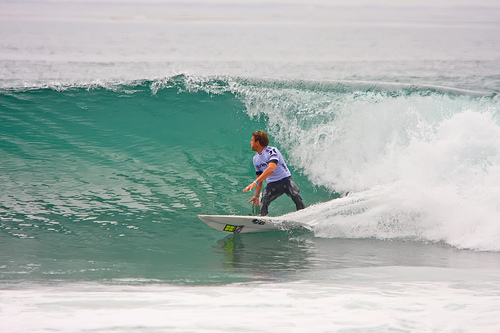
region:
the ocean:
[31, 21, 482, 318]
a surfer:
[184, 113, 381, 250]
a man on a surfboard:
[179, 113, 375, 240]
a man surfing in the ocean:
[186, 121, 403, 240]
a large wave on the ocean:
[33, 31, 473, 286]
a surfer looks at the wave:
[85, 86, 398, 247]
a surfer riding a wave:
[1, 71, 489, 244]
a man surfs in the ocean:
[187, 116, 394, 236]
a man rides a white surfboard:
[178, 103, 434, 241]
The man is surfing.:
[164, 120, 336, 246]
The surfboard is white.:
[195, 207, 323, 244]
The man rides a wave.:
[185, 110, 340, 248]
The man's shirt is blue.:
[245, 139, 295, 189]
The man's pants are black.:
[246, 170, 306, 221]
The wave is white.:
[317, 92, 494, 237]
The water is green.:
[0, 77, 195, 262]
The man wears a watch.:
[247, 174, 266, 189]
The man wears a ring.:
[237, 180, 252, 195]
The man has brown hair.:
[249, 124, 274, 149]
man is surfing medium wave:
[156, 107, 342, 272]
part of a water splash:
[411, 130, 477, 174]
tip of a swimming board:
[196, 205, 216, 222]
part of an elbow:
[263, 162, 278, 172]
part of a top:
[273, 155, 286, 170]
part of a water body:
[133, 254, 190, 302]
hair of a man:
[257, 127, 269, 144]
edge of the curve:
[203, 71, 278, 111]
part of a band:
[248, 175, 260, 190]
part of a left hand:
[237, 179, 257, 197]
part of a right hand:
[248, 196, 260, 208]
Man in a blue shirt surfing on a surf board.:
[242, 129, 307, 216]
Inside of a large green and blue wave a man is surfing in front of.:
[2, 78, 319, 260]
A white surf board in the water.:
[195, 213, 312, 234]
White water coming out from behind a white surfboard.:
[405, 126, 487, 199]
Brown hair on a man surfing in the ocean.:
[251, 129, 270, 148]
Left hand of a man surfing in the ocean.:
[242, 181, 257, 193]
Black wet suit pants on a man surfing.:
[258, 176, 305, 218]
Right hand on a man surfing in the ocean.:
[246, 197, 261, 206]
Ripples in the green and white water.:
[55, 177, 126, 227]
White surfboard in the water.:
[196, 213, 288, 235]